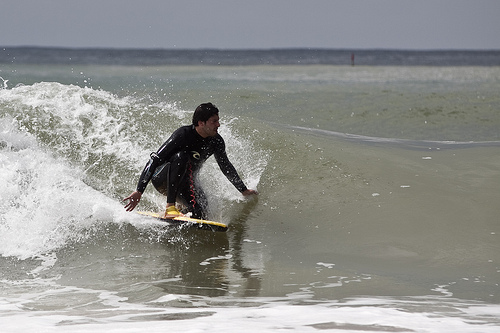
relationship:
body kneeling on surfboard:
[121, 100, 262, 225] [140, 202, 230, 233]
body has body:
[121, 100, 262, 225] [139, 113, 259, 220]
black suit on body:
[132, 124, 248, 221] [139, 113, 259, 220]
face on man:
[203, 111, 222, 134] [168, 92, 245, 160]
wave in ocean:
[21, 62, 168, 255] [0, 46, 500, 329]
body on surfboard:
[121, 100, 262, 225] [130, 197, 283, 267]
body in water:
[121, 100, 262, 225] [68, 73, 490, 300]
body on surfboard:
[121, 100, 262, 225] [158, 214, 230, 236]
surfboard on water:
[130, 197, 283, 267] [292, 165, 444, 244]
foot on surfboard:
[164, 202, 186, 221] [130, 209, 230, 236]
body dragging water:
[121, 100, 262, 225] [2, 44, 498, 331]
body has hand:
[121, 100, 262, 225] [243, 187, 258, 196]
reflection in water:
[159, 227, 255, 308] [2, 44, 498, 331]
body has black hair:
[121, 100, 262, 225] [191, 103, 220, 124]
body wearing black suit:
[121, 100, 262, 225] [155, 134, 231, 207]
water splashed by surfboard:
[1, 85, 227, 252] [159, 194, 224, 238]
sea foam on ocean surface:
[33, 87, 127, 249] [381, 44, 476, 119]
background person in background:
[348, 52, 357, 62] [0, 2, 498, 73]